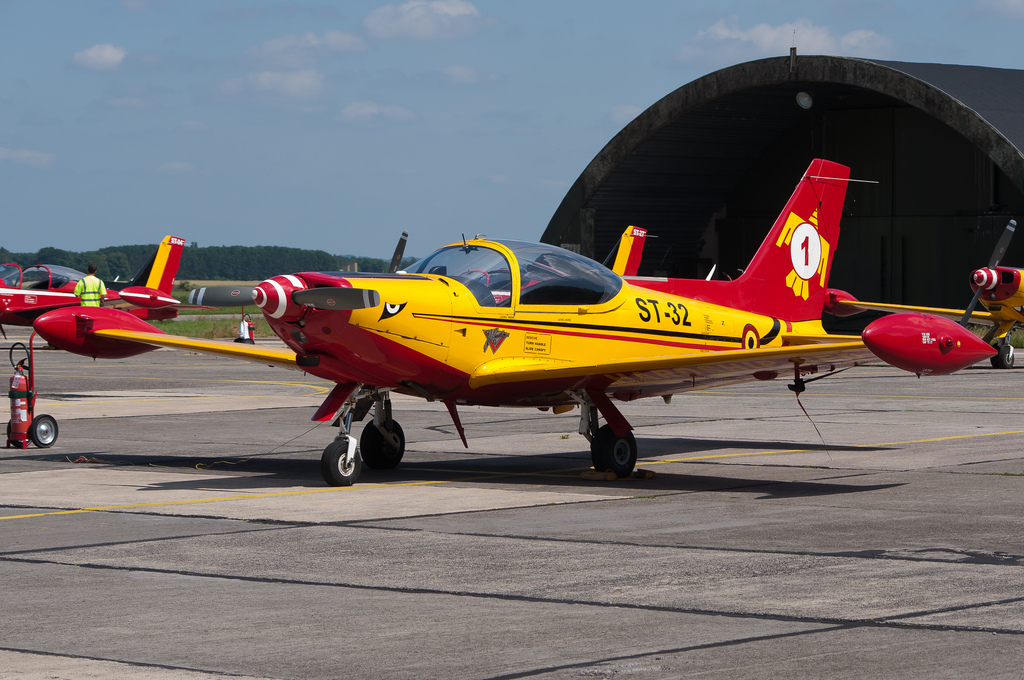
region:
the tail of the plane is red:
[753, 144, 874, 367]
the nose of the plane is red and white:
[204, 267, 366, 338]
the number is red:
[713, 175, 851, 286]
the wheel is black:
[291, 413, 383, 508]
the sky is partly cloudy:
[86, 1, 543, 221]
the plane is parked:
[128, 90, 942, 523]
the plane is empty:
[359, 198, 644, 326]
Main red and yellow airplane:
[34, 154, 1008, 481]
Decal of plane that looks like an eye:
[378, 295, 413, 325]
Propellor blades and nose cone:
[188, 273, 382, 319]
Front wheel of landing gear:
[323, 406, 368, 486]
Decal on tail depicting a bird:
[769, 198, 839, 300]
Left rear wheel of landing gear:
[573, 378, 641, 480]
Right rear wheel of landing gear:
[353, 386, 408, 486]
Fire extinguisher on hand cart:
[1, 314, 60, 452]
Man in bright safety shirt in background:
[72, 263, 111, 309]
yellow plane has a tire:
[591, 427, 637, 478]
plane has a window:
[482, 238, 616, 306]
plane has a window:
[419, 248, 512, 306]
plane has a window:
[52, 263, 90, 292]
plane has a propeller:
[291, 284, 384, 308]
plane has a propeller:
[172, 288, 258, 307]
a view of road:
[458, 538, 727, 656]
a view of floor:
[356, 474, 613, 588]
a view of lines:
[391, 544, 663, 663]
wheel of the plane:
[280, 380, 571, 570]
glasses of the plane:
[347, 203, 693, 378]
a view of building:
[537, 60, 1005, 310]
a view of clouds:
[202, 81, 336, 136]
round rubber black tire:
[29, 409, 64, 449]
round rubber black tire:
[317, 431, 362, 490]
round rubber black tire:
[361, 407, 410, 474]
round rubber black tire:
[589, 418, 632, 489]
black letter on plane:
[633, 289, 654, 325]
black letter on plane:
[643, 287, 666, 332]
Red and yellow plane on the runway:
[171, 129, 880, 521]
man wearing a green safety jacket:
[69, 271, 117, 309]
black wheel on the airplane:
[585, 416, 643, 465]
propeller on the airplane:
[151, 271, 371, 330]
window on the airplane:
[416, 228, 613, 324]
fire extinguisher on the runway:
[8, 360, 46, 456]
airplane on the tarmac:
[856, 187, 1015, 344]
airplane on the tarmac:
[15, 246, 187, 330]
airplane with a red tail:
[660, 152, 851, 309]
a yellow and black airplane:
[33, 157, 992, 489]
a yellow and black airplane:
[6, 223, 177, 322]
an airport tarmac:
[9, 326, 1019, 677]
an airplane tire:
[587, 409, 645, 479]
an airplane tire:
[367, 406, 421, 477]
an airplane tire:
[316, 424, 365, 486]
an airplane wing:
[455, 310, 974, 416]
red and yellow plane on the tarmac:
[210, 173, 914, 482]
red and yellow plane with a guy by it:
[13, 220, 136, 371]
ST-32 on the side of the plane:
[640, 292, 698, 330]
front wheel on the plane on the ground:
[307, 425, 378, 494]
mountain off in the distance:
[220, 226, 332, 265]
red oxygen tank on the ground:
[10, 323, 55, 458]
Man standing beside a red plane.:
[68, 260, 119, 309]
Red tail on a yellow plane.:
[740, 155, 867, 315]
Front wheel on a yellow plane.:
[310, 410, 378, 483]